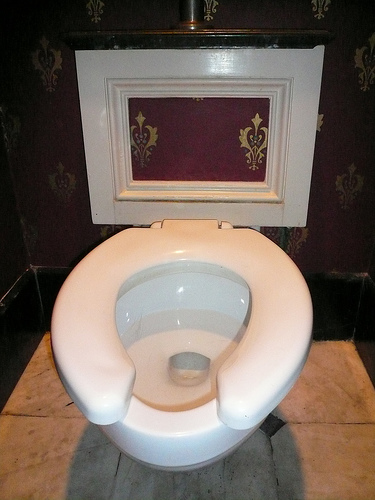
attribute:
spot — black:
[258, 413, 286, 436]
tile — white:
[0, 320, 371, 496]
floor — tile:
[6, 430, 374, 498]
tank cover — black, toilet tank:
[57, 30, 326, 49]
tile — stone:
[299, 385, 353, 441]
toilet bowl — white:
[51, 220, 313, 471]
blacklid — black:
[67, 28, 338, 52]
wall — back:
[5, 7, 371, 247]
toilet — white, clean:
[39, 213, 321, 480]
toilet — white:
[29, 109, 318, 475]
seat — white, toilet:
[45, 212, 321, 427]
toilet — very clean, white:
[47, 29, 338, 475]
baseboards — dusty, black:
[0, 263, 374, 411]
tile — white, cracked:
[293, 371, 361, 470]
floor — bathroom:
[7, 374, 59, 494]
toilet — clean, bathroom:
[48, 178, 329, 473]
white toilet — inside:
[48, 206, 321, 477]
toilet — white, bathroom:
[42, 225, 308, 478]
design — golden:
[124, 111, 163, 173]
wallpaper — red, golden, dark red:
[1, 0, 374, 268]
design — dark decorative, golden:
[128, 110, 158, 165]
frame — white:
[75, 43, 317, 230]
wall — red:
[3, 4, 363, 272]